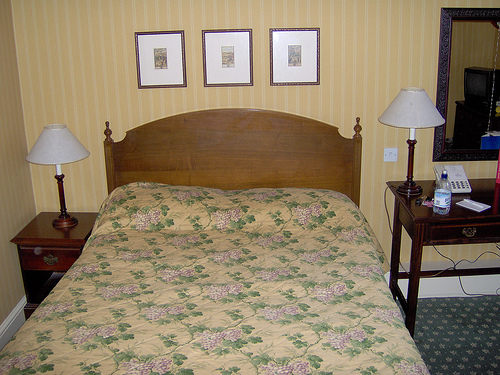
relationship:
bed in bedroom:
[4, 106, 434, 374] [0, 1, 499, 372]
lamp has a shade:
[375, 81, 450, 200] [372, 84, 449, 136]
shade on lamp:
[372, 84, 449, 136] [375, 81, 450, 200]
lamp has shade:
[375, 81, 450, 200] [372, 84, 449, 136]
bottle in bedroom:
[427, 166, 456, 218] [0, 1, 499, 372]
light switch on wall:
[379, 142, 403, 166] [0, 1, 499, 328]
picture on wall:
[129, 28, 191, 94] [0, 1, 499, 328]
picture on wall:
[197, 26, 258, 91] [0, 1, 499, 328]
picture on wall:
[265, 23, 326, 91] [0, 1, 499, 328]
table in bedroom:
[384, 173, 499, 343] [0, 1, 499, 372]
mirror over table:
[430, 4, 499, 165] [384, 173, 499, 343]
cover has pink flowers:
[2, 179, 435, 374] [242, 259, 302, 288]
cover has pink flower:
[2, 179, 435, 374] [182, 319, 251, 359]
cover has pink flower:
[2, 179, 435, 374] [203, 202, 248, 234]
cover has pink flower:
[2, 179, 435, 374] [356, 299, 407, 330]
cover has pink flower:
[2, 179, 435, 374] [90, 272, 150, 307]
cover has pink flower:
[2, 179, 435, 374] [121, 204, 168, 235]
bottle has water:
[427, 166, 456, 218] [430, 204, 454, 219]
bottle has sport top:
[427, 166, 456, 218] [439, 167, 451, 181]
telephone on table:
[431, 160, 475, 198] [384, 173, 499, 343]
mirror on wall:
[430, 4, 499, 165] [0, 1, 499, 328]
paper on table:
[453, 194, 495, 217] [384, 173, 499, 343]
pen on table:
[460, 195, 488, 212] [384, 173, 499, 343]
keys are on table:
[411, 192, 437, 211] [384, 173, 499, 343]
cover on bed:
[2, 179, 435, 374] [4, 106, 434, 374]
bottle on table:
[427, 166, 456, 218] [384, 173, 499, 343]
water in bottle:
[430, 204, 454, 219] [427, 166, 456, 218]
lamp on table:
[375, 81, 450, 200] [384, 173, 499, 343]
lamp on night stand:
[22, 119, 94, 233] [9, 208, 100, 323]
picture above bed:
[129, 28, 191, 94] [4, 106, 434, 374]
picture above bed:
[197, 26, 258, 91] [4, 106, 434, 374]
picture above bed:
[265, 23, 326, 91] [4, 106, 434, 374]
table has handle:
[384, 173, 499, 343] [458, 224, 481, 241]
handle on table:
[458, 224, 481, 241] [384, 173, 499, 343]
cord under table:
[382, 184, 500, 302] [384, 173, 499, 343]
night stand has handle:
[9, 208, 100, 323] [36, 251, 63, 271]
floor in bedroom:
[395, 292, 499, 374] [0, 1, 499, 372]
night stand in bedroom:
[9, 208, 100, 323] [0, 1, 499, 372]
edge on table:
[407, 211, 427, 233] [384, 173, 499, 343]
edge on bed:
[397, 354, 435, 374] [4, 106, 434, 374]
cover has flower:
[2, 179, 435, 374] [186, 322, 247, 357]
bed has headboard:
[4, 106, 434, 374] [98, 110, 366, 207]